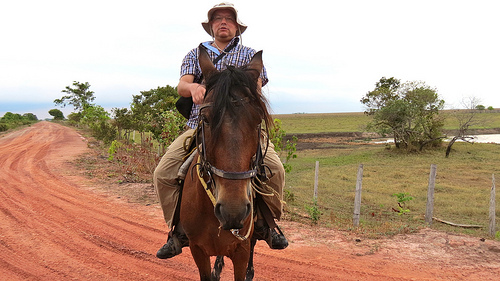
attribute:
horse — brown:
[180, 46, 275, 280]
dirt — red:
[0, 119, 499, 280]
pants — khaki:
[154, 126, 284, 231]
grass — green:
[262, 108, 499, 243]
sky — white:
[2, 0, 499, 122]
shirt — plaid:
[179, 37, 269, 130]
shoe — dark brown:
[158, 233, 191, 258]